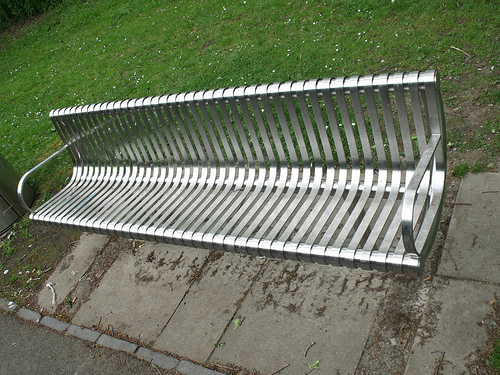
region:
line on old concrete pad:
[53, 238, 110, 318]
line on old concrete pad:
[147, 250, 214, 347]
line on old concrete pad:
[204, 255, 266, 367]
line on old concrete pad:
[352, 275, 393, 373]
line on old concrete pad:
[402, 274, 436, 372]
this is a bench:
[0, 37, 495, 293]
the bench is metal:
[10, 52, 477, 334]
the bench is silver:
[12, 53, 477, 293]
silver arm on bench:
[369, 118, 454, 260]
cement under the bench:
[22, 240, 434, 372]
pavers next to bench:
[11, 299, 171, 374]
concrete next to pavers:
[3, 322, 101, 374]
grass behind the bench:
[15, 15, 480, 151]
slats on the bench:
[15, 71, 455, 271]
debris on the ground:
[37, 282, 213, 362]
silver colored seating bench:
[12, 73, 455, 269]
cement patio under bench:
[9, 163, 494, 374]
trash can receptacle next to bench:
[1, 151, 38, 241]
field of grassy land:
[4, 5, 494, 197]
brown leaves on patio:
[6, 235, 498, 373]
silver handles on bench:
[396, 127, 453, 253]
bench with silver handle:
[10, 148, 71, 210]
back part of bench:
[50, 68, 452, 171]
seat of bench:
[28, 165, 446, 277]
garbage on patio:
[36, 281, 61, 314]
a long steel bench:
[11, 65, 443, 272]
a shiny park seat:
[10, 63, 465, 271]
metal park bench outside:
[4, 68, 476, 276]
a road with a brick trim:
[1, 287, 226, 372]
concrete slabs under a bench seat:
[50, 154, 498, 371]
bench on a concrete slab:
[14, 67, 495, 374]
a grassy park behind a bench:
[1, 4, 498, 304]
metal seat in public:
[12, 67, 457, 278]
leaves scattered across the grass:
[55, 7, 383, 72]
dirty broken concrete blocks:
[107, 257, 401, 372]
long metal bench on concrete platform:
[15, 67, 446, 272]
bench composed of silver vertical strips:
[12, 65, 452, 282]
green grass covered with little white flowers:
[5, 5, 490, 305]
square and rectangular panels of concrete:
[20, 165, 495, 370]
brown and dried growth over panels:
[31, 165, 491, 365]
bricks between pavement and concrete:
[7, 292, 221, 369]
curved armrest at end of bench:
[399, 126, 443, 261]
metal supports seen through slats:
[65, 161, 417, 260]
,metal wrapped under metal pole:
[29, 210, 421, 272]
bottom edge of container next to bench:
[3, 151, 42, 248]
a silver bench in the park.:
[13, 97, 465, 277]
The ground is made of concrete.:
[31, 258, 296, 373]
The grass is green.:
[83, 18, 416, 85]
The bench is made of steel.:
[188, 78, 450, 261]